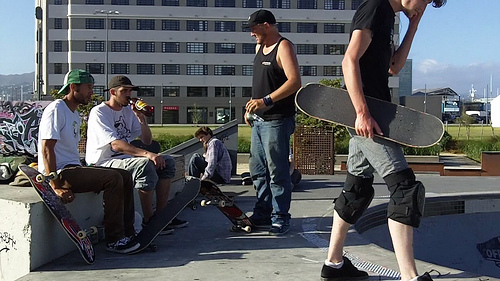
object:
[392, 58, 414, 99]
building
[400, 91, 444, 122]
building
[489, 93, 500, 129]
building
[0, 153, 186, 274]
concrete wall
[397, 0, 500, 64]
blue sky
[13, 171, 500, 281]
ground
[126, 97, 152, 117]
bottle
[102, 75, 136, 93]
hat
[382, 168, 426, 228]
knee pads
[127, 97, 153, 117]
beverage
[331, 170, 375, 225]
kneepad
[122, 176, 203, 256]
skateboard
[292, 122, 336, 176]
waste bin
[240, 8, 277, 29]
black cap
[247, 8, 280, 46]
man's head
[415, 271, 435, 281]
shoes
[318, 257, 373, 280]
foot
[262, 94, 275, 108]
wrist band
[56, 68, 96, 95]
hat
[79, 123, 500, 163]
green grass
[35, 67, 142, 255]
boy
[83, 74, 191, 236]
boy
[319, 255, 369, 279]
shoe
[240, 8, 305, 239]
man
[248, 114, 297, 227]
blue jeans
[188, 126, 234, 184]
boy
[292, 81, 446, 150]
skateboard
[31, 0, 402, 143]
building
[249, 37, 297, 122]
black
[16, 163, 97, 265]
skateboard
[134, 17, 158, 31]
window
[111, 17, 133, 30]
window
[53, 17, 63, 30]
window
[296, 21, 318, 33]
window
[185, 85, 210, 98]
window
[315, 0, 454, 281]
man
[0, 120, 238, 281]
wall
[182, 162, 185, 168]
stairs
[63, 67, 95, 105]
boy's head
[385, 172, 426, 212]
boy's knees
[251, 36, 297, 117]
vest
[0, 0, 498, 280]
photo